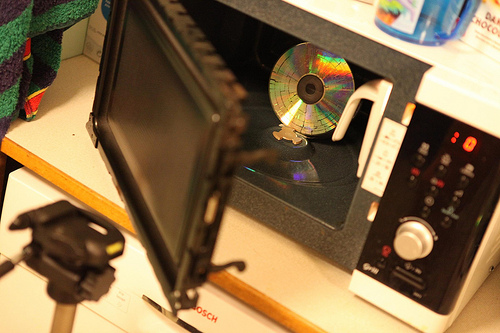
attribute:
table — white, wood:
[32, 67, 382, 326]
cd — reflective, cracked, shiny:
[269, 26, 369, 141]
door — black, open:
[103, 8, 237, 283]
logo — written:
[191, 298, 224, 324]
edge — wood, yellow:
[299, 238, 433, 332]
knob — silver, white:
[394, 218, 434, 259]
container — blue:
[376, 2, 476, 61]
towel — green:
[3, 5, 90, 138]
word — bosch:
[189, 301, 220, 326]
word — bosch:
[175, 291, 222, 325]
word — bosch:
[184, 298, 220, 326]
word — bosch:
[185, 301, 215, 325]